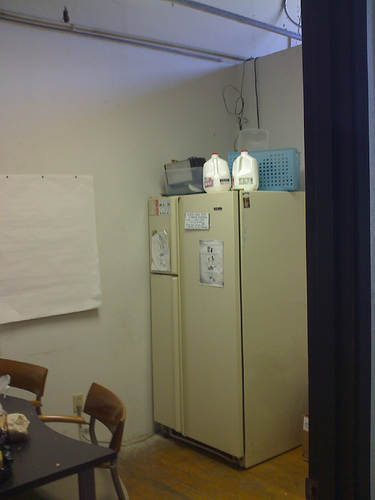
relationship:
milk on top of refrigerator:
[202, 150, 235, 192] [145, 189, 306, 463]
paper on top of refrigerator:
[196, 243, 226, 290] [145, 189, 306, 463]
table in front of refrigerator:
[1, 390, 106, 495] [145, 189, 306, 463]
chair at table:
[44, 382, 160, 493] [1, 390, 106, 495]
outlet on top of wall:
[70, 393, 88, 417] [52, 360, 114, 415]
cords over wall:
[221, 60, 285, 128] [192, 57, 302, 145]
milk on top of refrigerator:
[234, 148, 255, 191] [145, 189, 306, 463]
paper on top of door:
[196, 243, 226, 290] [180, 196, 243, 448]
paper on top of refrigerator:
[150, 232, 175, 270] [145, 189, 306, 463]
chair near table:
[0, 353, 44, 413] [1, 390, 106, 495]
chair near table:
[44, 382, 160, 493] [1, 390, 106, 495]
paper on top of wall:
[3, 171, 104, 326] [3, 125, 95, 173]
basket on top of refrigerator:
[228, 148, 303, 192] [145, 189, 306, 463]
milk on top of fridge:
[202, 150, 235, 192] [145, 189, 306, 463]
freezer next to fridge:
[147, 200, 179, 431] [180, 196, 243, 448]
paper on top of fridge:
[196, 243, 226, 290] [145, 189, 306, 463]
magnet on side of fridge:
[245, 197, 252, 209] [145, 189, 306, 463]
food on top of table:
[6, 409, 31, 444] [1, 390, 106, 495]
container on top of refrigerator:
[234, 148, 255, 191] [145, 189, 306, 463]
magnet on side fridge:
[245, 197, 252, 209] [145, 189, 306, 463]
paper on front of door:
[196, 243, 226, 290] [180, 196, 243, 448]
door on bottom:
[150, 273, 180, 431] [147, 200, 179, 431]